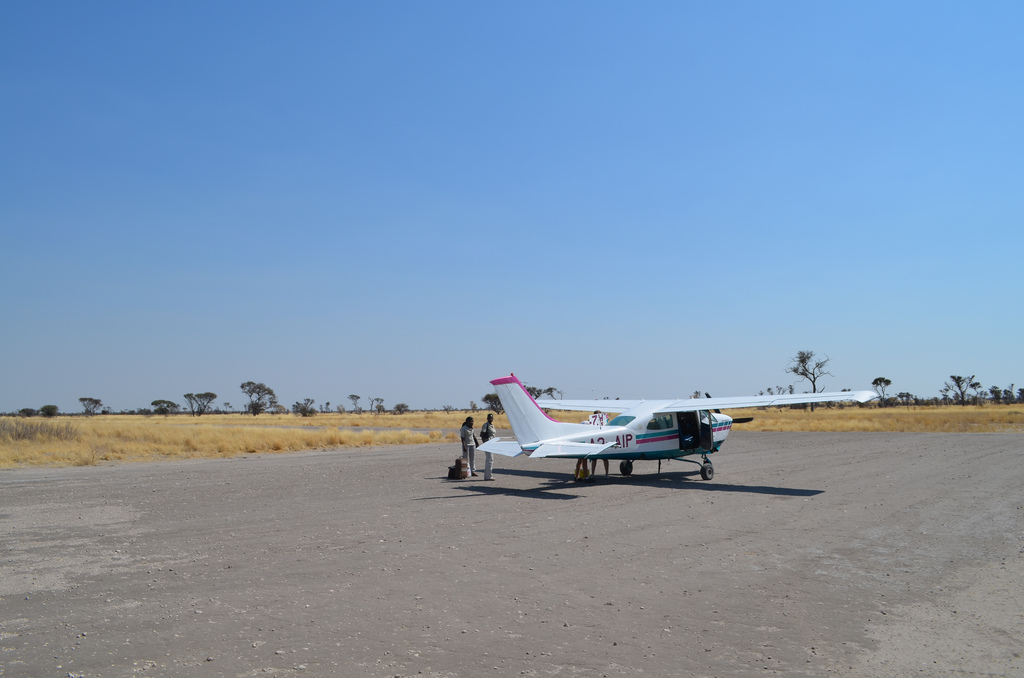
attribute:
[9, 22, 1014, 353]
sky — blue, clear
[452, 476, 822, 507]
shadow — of plane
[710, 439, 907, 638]
tarmac — grey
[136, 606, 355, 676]
pebbles — small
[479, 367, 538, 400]
color — pink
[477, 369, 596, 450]
wing — plane's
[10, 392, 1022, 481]
grass — yellow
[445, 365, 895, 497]
plane — small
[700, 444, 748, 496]
wheel — black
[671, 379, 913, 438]
wing — white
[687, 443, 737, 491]
wheel — black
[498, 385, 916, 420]
wings — white 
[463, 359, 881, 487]
plane — one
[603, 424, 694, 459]
letters — black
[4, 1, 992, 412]
sky — clear, blue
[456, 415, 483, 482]
person — standing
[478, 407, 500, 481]
person — standing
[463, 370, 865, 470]
plane — one